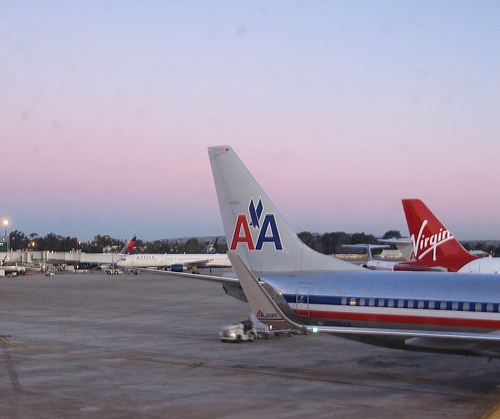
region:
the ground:
[80, 310, 142, 358]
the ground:
[125, 298, 192, 395]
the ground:
[87, 272, 231, 409]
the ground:
[120, 341, 178, 408]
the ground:
[82, 330, 169, 415]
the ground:
[165, 355, 226, 412]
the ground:
[140, 314, 240, 415]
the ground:
[135, 352, 200, 404]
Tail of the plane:
[208, 136, 344, 265]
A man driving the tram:
[213, 313, 260, 345]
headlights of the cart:
[210, 328, 239, 344]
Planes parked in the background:
[30, 243, 225, 271]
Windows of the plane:
[336, 289, 498, 316]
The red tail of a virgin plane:
[405, 199, 477, 271]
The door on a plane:
[291, 277, 315, 316]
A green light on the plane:
[305, 324, 322, 339]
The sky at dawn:
[11, 136, 176, 218]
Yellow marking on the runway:
[0, 322, 60, 359]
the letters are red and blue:
[216, 192, 295, 254]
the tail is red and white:
[381, 188, 473, 283]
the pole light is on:
[1, 213, 14, 236]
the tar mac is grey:
[42, 343, 135, 384]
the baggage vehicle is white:
[214, 315, 269, 362]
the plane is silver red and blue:
[193, 140, 496, 343]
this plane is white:
[113, 249, 233, 274]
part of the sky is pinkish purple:
[6, 105, 109, 174]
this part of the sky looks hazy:
[330, 15, 450, 63]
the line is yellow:
[3, 322, 38, 356]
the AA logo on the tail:
[224, 191, 286, 261]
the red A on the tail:
[227, 213, 255, 253]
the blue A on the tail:
[254, 213, 284, 252]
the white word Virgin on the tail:
[408, 217, 453, 262]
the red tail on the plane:
[397, 190, 469, 277]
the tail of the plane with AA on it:
[204, 141, 299, 272]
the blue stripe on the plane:
[283, 287, 498, 311]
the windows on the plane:
[291, 297, 498, 313]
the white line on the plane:
[290, 299, 498, 318]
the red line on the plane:
[295, 310, 492, 332]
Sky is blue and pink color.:
[62, 25, 408, 180]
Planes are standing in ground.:
[0, 235, 493, 365]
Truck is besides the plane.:
[208, 310, 269, 347]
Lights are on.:
[1, 217, 177, 254]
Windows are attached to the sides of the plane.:
[330, 282, 497, 317]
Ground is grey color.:
[51, 305, 147, 385]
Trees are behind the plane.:
[15, 226, 190, 247]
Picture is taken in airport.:
[13, 70, 478, 395]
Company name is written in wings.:
[227, 200, 457, 271]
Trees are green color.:
[7, 226, 177, 253]